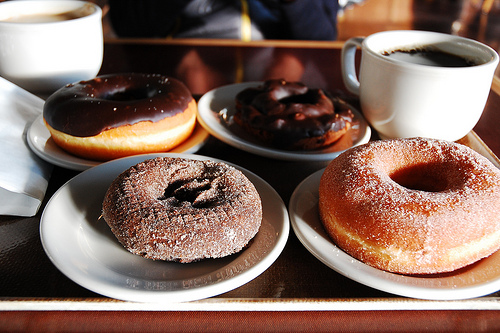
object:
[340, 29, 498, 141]
cup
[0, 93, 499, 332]
table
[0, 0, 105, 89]
cup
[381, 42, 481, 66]
dark coffee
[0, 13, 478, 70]
coffee and milk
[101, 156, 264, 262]
donut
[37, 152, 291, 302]
plate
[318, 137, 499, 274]
donut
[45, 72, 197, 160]
donut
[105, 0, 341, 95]
person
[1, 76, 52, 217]
napkin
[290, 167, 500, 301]
plate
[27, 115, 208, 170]
plate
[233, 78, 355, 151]
donut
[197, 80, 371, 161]
plate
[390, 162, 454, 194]
hole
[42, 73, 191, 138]
chocolate frosting